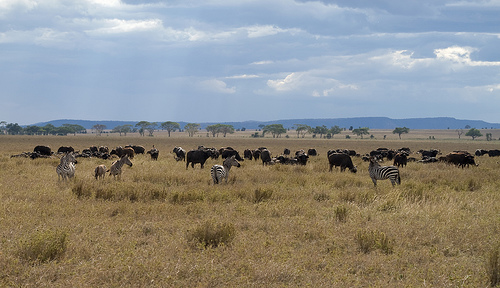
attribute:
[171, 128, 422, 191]
animals — standing together, in the wild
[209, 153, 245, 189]
zebra — in the center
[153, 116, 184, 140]
tree — far away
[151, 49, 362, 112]
light — from the sun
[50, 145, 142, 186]
zebras — in the foreground, watching around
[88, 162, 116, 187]
zebra — grazing grass, black, white, eating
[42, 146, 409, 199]
five zebras — here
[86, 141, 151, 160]
buffalos — eating